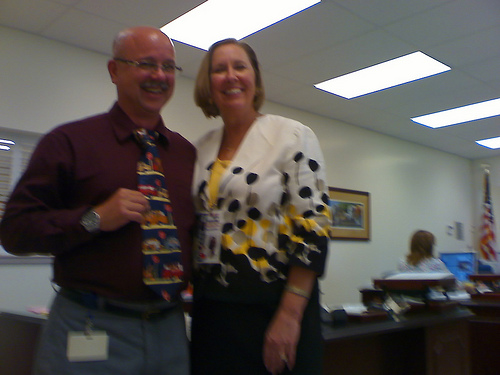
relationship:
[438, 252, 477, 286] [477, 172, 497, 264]
monitor near flag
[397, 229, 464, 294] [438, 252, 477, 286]
lady sitting in front of monitor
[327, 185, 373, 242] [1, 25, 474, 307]
frame on wall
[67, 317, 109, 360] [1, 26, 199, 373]
id on man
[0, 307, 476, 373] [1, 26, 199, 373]
desk behind man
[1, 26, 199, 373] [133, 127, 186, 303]
man wearing tie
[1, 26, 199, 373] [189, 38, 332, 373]
man standing with woman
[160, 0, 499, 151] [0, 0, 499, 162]
lights in ceiling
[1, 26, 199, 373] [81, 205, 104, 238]
man has a watch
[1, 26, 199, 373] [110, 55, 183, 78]
man wearing glasses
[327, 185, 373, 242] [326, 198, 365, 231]
frame around picture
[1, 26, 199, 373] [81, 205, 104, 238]
man wearing watch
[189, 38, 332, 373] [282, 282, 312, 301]
woman wearing bracelet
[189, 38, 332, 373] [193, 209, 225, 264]
woman wearing id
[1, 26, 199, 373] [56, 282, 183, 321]
man wearing belt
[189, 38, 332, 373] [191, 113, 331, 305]
woman wearing jacket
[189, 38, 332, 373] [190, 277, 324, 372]
woman wearing pants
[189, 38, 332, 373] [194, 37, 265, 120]
woman has hair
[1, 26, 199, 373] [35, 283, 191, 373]
man wearing pants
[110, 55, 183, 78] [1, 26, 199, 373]
glasses on man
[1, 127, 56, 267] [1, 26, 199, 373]
window behind man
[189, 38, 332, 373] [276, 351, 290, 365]
woman wearing ring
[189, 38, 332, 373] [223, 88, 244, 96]
woman has teeth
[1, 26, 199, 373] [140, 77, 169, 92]
man has a mustache